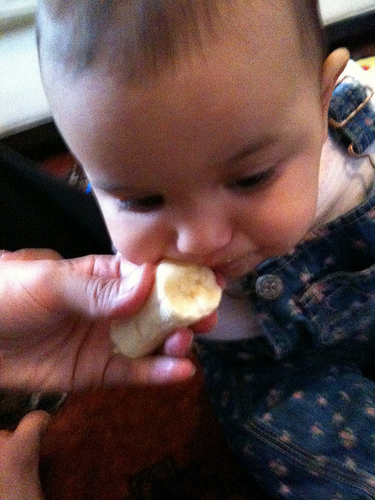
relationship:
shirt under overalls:
[107, 57, 372, 336] [190, 78, 369, 496]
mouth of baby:
[212, 241, 257, 275] [36, 2, 373, 497]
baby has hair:
[36, 2, 373, 497] [35, 1, 327, 90]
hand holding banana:
[3, 254, 226, 386] [111, 257, 221, 360]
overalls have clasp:
[190, 78, 369, 496] [207, 261, 285, 302]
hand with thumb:
[3, 254, 226, 386] [40, 259, 153, 319]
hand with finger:
[3, 254, 226, 386] [100, 349, 197, 386]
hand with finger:
[3, 254, 226, 386] [158, 324, 194, 358]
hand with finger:
[3, 254, 226, 386] [188, 304, 222, 333]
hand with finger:
[3, 254, 226, 386] [210, 272, 226, 292]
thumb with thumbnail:
[40, 259, 153, 319] [115, 263, 143, 292]